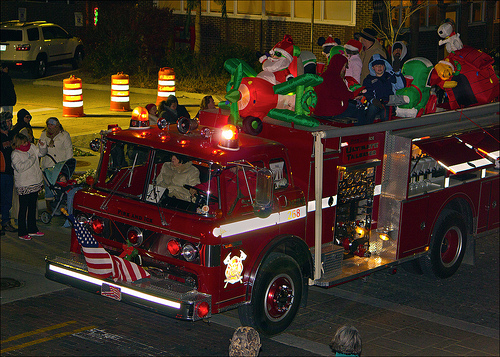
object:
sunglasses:
[263, 49, 281, 58]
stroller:
[38, 152, 81, 222]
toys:
[364, 60, 399, 117]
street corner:
[1, 89, 79, 240]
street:
[7, 90, 493, 352]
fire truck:
[34, 45, 490, 352]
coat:
[7, 145, 52, 197]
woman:
[0, 128, 49, 246]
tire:
[255, 248, 306, 329]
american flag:
[58, 205, 153, 281]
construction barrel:
[53, 58, 185, 118]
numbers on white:
[285, 208, 302, 221]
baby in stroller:
[55, 172, 92, 202]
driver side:
[175, 171, 283, 229]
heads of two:
[228, 305, 368, 355]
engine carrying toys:
[204, 18, 497, 126]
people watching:
[38, 118, 73, 199]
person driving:
[195, 153, 259, 218]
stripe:
[449, 155, 488, 175]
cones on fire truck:
[60, 75, 88, 119]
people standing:
[5, 126, 45, 240]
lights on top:
[218, 126, 242, 154]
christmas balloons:
[222, 65, 324, 123]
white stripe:
[215, 212, 278, 239]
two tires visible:
[243, 221, 475, 335]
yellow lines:
[1, 335, 53, 355]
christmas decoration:
[437, 24, 499, 101]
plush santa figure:
[219, 36, 319, 126]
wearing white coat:
[37, 128, 73, 161]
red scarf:
[20, 145, 30, 152]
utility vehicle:
[2, 18, 91, 69]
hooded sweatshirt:
[316, 52, 350, 118]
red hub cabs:
[436, 229, 466, 271]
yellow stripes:
[1, 325, 53, 343]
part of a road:
[357, 287, 499, 353]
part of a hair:
[333, 326, 364, 355]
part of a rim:
[255, 236, 297, 249]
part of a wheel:
[441, 215, 471, 273]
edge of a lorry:
[40, 260, 196, 310]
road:
[386, 286, 480, 357]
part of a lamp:
[220, 122, 247, 152]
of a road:
[0, 290, 107, 355]